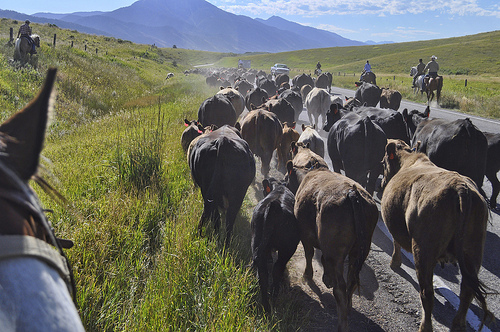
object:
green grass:
[399, 16, 498, 109]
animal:
[0, 65, 85, 330]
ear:
[0, 65, 56, 173]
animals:
[286, 161, 373, 332]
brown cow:
[276, 117, 299, 169]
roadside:
[53, 82, 257, 322]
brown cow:
[292, 151, 379, 320]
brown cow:
[241, 104, 283, 177]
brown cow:
[376, 133, 489, 332]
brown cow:
[211, 86, 246, 123]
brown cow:
[261, 97, 295, 125]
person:
[11, 18, 35, 54]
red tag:
[266, 184, 271, 192]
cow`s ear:
[262, 178, 270, 188]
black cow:
[249, 176, 298, 321]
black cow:
[187, 121, 255, 252]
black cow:
[198, 95, 236, 129]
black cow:
[355, 81, 382, 107]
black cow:
[323, 103, 387, 198]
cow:
[402, 104, 485, 196]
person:
[411, 58, 425, 88]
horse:
[410, 66, 424, 95]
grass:
[86, 133, 186, 223]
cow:
[264, 99, 297, 126]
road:
[373, 247, 390, 318]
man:
[359, 60, 372, 81]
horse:
[360, 71, 376, 85]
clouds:
[233, 0, 492, 33]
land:
[280, 18, 494, 116]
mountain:
[3, 0, 376, 51]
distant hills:
[61, 0, 400, 48]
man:
[420, 55, 439, 94]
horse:
[423, 74, 444, 107]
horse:
[12, 31, 41, 67]